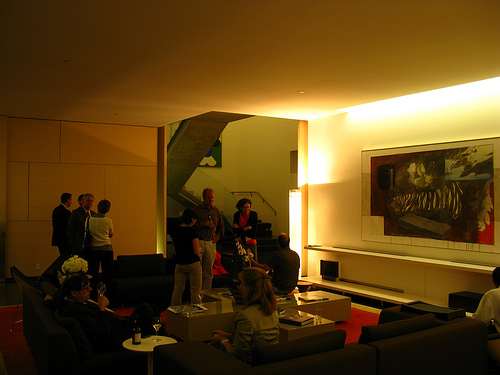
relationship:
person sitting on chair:
[210, 266, 283, 357] [38, 281, 498, 371]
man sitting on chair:
[55, 274, 162, 340] [38, 281, 498, 371]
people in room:
[172, 184, 282, 288] [1, 3, 496, 363]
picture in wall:
[360, 137, 499, 254] [300, 85, 498, 321]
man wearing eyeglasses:
[55, 274, 162, 340] [79, 280, 93, 292]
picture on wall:
[354, 128, 499, 253] [300, 85, 498, 321]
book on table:
[179, 284, 293, 315] [195, 291, 412, 348]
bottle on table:
[131, 318, 139, 342] [104, 291, 332, 372]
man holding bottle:
[190, 183, 230, 312] [196, 210, 213, 240]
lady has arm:
[232, 222, 240, 230] [229, 197, 265, 249]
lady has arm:
[232, 222, 240, 230] [245, 222, 256, 231]